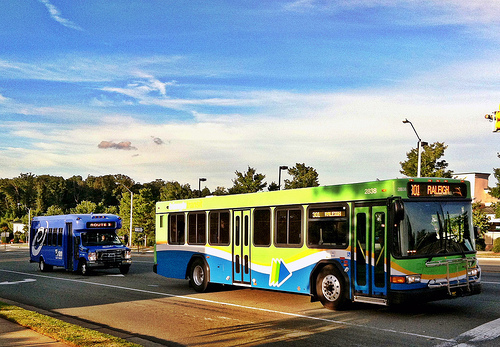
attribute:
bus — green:
[144, 186, 494, 311]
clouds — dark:
[94, 132, 173, 158]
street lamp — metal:
[400, 116, 422, 177]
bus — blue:
[10, 173, 498, 318]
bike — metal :
[421, 247, 481, 297]